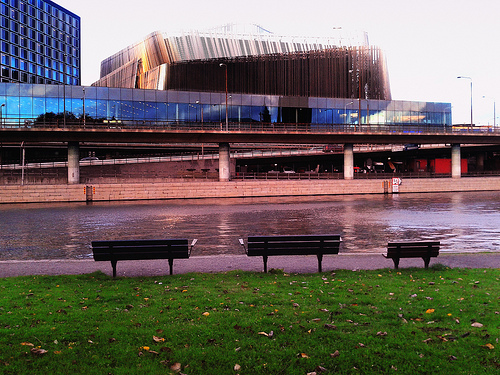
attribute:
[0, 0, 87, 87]
building — tall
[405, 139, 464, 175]
truck — red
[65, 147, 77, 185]
pillar — stone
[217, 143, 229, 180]
pillar — stone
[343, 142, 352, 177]
pillar — stone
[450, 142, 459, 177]
pillar — stone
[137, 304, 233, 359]
leaves — dry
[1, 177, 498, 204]
wall — brick, short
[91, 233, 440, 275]
benches — empty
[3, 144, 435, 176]
ramp — parking garage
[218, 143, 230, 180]
column — concrete, thick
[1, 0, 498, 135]
sky — blue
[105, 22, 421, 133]
design — modern 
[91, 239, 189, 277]
bench — empty, are empty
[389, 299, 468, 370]
leaves — dry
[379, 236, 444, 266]
bench — small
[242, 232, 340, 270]
bench — empty, three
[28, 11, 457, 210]
building — office, taller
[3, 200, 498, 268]
lake — large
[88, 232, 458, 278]
benches — adult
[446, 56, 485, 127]
lights — street, tall